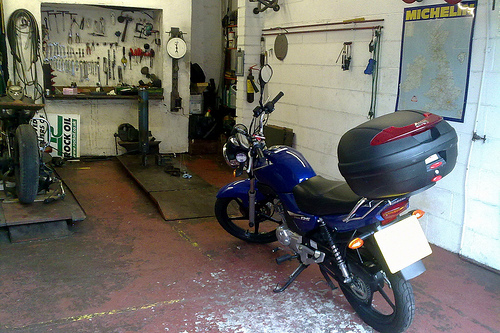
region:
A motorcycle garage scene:
[2, 2, 494, 327]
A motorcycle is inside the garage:
[211, 63, 458, 330]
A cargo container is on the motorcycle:
[336, 107, 461, 204]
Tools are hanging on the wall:
[39, 1, 161, 91]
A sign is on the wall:
[395, 3, 480, 118]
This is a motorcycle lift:
[113, 83, 243, 226]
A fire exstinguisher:
[242, 62, 259, 103]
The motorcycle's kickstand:
[267, 262, 338, 297]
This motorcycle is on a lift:
[0, 77, 88, 242]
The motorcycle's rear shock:
[314, 217, 355, 289]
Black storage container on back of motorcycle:
[335, 105, 460, 201]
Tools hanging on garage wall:
[42, 8, 163, 93]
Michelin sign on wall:
[395, 3, 475, 123]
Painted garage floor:
[97, 250, 259, 326]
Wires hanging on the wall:
[6, 7, 42, 104]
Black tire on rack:
[12, 123, 42, 208]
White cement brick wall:
[294, 73, 334, 129]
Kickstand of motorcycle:
[276, 232, 339, 293]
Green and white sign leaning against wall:
[31, 114, 80, 160]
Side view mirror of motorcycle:
[258, 63, 272, 104]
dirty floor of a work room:
[37, 245, 229, 320]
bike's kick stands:
[267, 265, 332, 295]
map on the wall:
[396, 6, 468, 111]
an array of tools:
[45, 6, 160, 81]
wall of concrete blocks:
[290, 75, 332, 151]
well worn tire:
[11, 120, 38, 200]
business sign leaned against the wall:
[36, 111, 81, 157]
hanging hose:
[10, 7, 40, 92]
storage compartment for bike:
[340, 110, 455, 195]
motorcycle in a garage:
[211, 90, 461, 327]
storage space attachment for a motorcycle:
[336, 108, 456, 198]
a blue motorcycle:
[214, 66, 461, 330]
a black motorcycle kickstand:
[271, 258, 308, 295]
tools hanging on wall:
[46, 9, 162, 89]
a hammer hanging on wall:
[121, 12, 134, 40]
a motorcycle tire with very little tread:
[11, 119, 43, 209]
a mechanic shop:
[6, 1, 499, 330]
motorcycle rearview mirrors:
[228, 58, 275, 162]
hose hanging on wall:
[5, 6, 50, 146]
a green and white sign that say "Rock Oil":
[31, 111, 79, 160]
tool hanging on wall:
[43, 5, 55, 31]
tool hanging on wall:
[121, 43, 131, 75]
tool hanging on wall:
[88, 57, 96, 82]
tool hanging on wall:
[74, 58, 85, 87]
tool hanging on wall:
[128, 51, 132, 71]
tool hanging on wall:
[66, 27, 71, 42]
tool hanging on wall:
[121, 15, 130, 46]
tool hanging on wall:
[134, 23, 145, 38]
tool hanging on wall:
[86, 43, 95, 54]